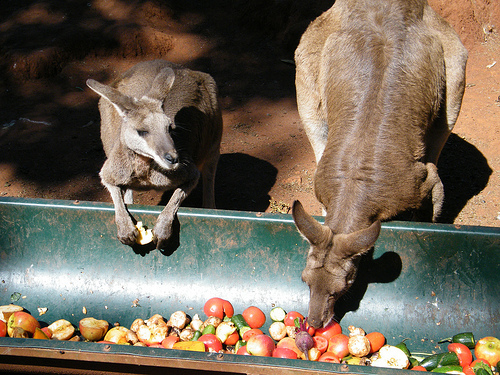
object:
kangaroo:
[85, 59, 227, 248]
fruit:
[133, 221, 156, 245]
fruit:
[8, 308, 39, 340]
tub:
[0, 197, 500, 375]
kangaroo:
[294, 0, 469, 330]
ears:
[85, 77, 138, 120]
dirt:
[0, 0, 499, 226]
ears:
[291, 201, 333, 254]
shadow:
[159, 153, 279, 213]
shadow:
[424, 130, 491, 224]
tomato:
[311, 335, 328, 354]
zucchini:
[447, 332, 475, 347]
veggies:
[203, 296, 234, 318]